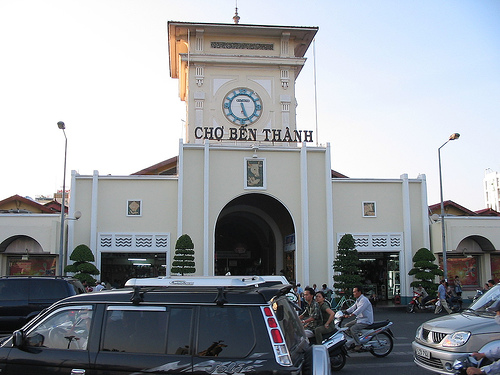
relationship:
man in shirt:
[342, 282, 376, 353] [343, 296, 378, 331]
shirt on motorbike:
[343, 296, 378, 331] [330, 308, 395, 357]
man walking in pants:
[433, 277, 454, 314] [433, 300, 453, 316]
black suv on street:
[0, 274, 333, 375] [338, 312, 473, 373]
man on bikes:
[342, 282, 376, 353] [337, 321, 387, 363]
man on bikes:
[342, 282, 376, 353] [309, 290, 339, 361]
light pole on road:
[54, 117, 70, 276] [334, 312, 454, 375]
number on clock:
[238, 87, 244, 94] [221, 88, 265, 127]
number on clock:
[253, 97, 259, 104] [221, 88, 265, 127]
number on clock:
[253, 104, 259, 114] [221, 88, 265, 127]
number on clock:
[252, 113, 259, 123] [221, 88, 265, 127]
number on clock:
[238, 117, 246, 127] [221, 88, 265, 127]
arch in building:
[214, 185, 299, 275] [2, 7, 498, 306]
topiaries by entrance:
[331, 232, 367, 307] [339, 248, 415, 318]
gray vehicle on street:
[408, 287, 499, 372] [343, 354, 415, 373]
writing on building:
[195, 125, 313, 142] [2, 7, 498, 306]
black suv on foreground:
[41, 274, 310, 336] [2, 297, 492, 373]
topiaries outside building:
[412, 248, 443, 303] [2, 7, 498, 306]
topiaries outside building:
[331, 232, 364, 294] [2, 7, 498, 306]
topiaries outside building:
[173, 234, 192, 271] [2, 7, 498, 306]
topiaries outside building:
[67, 245, 97, 277] [2, 7, 498, 306]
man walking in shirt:
[433, 278, 454, 315] [434, 283, 449, 302]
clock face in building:
[218, 84, 265, 129] [159, 10, 337, 192]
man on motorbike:
[342, 282, 376, 353] [330, 308, 395, 357]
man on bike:
[342, 282, 376, 353] [302, 309, 352, 371]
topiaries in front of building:
[331, 232, 367, 307] [10, 15, 499, 265]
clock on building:
[181, 74, 308, 151] [66, 13, 432, 305]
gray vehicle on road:
[408, 282, 500, 374] [298, 300, 448, 373]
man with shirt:
[342, 282, 378, 343] [340, 293, 378, 323]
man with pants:
[342, 282, 378, 343] [339, 320, 369, 338]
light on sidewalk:
[432, 130, 462, 308] [379, 294, 408, 312]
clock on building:
[221, 85, 265, 128] [66, 13, 432, 305]